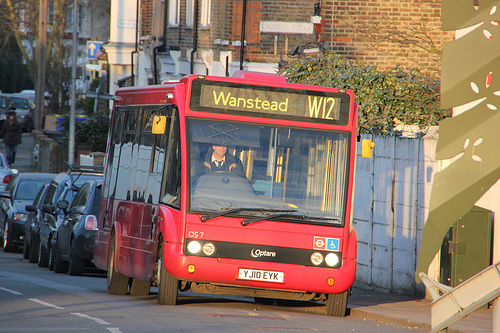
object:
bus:
[93, 70, 356, 318]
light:
[185, 239, 345, 267]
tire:
[152, 249, 180, 306]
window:
[182, 115, 348, 230]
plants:
[275, 41, 442, 133]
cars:
[0, 163, 104, 276]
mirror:
[361, 139, 375, 159]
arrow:
[87, 42, 98, 59]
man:
[200, 144, 246, 177]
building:
[105, 0, 441, 297]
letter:
[212, 89, 341, 120]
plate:
[238, 268, 285, 283]